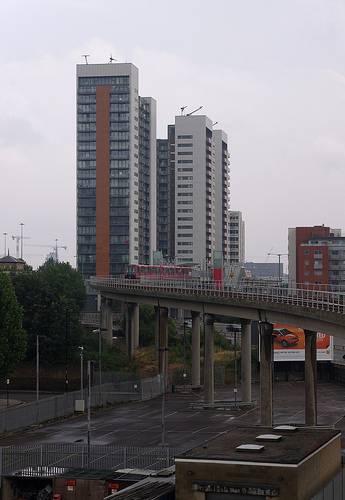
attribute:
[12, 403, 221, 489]
lot — parking 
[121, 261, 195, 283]
train — red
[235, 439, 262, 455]
skylight — rectangular , opaque 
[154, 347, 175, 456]
light pole — tall , metal 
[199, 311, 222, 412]
support column — raised 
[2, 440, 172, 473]
fence — long , metal 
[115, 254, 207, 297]
train — red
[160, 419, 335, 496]
building — brown, industrial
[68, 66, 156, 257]
building — tall, multi story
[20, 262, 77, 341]
tree — tall, lush, green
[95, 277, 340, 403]
railway — elevated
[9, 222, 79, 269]
cranes — construction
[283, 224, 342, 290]
buildings — apartment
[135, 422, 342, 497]
building — low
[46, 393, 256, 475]
parking lot — empty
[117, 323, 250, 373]
land — undeveloped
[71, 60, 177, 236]
skyscrapers — large, towering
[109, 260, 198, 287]
train — red, commuter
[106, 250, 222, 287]
train — commuter, overhead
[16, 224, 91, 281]
crane — new, building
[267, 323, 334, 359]
billboard — ORANGE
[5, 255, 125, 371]
trees — LARGE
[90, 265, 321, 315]
tracks — TRAIN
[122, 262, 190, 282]
train — RED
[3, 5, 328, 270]
sky — grey, CLOUDY